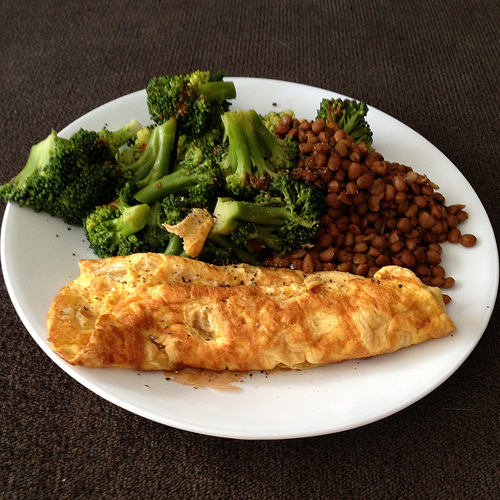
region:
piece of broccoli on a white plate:
[0, 120, 112, 217]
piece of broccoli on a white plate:
[142, 66, 244, 131]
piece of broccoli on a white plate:
[315, 94, 377, 145]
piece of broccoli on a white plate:
[101, 116, 146, 156]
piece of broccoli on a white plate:
[79, 194, 157, 256]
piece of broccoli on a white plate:
[131, 140, 225, 217]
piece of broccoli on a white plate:
[195, 168, 319, 267]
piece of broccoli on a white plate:
[205, 102, 299, 198]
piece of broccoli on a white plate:
[120, 115, 185, 191]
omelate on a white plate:
[45, 244, 458, 384]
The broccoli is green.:
[140, 61, 243, 136]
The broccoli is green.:
[71, 116, 145, 166]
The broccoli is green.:
[3, 124, 78, 213]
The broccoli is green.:
[83, 194, 150, 255]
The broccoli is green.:
[205, 176, 322, 263]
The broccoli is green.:
[121, 132, 221, 207]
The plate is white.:
[1, 67, 498, 442]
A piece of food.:
[353, 237, 370, 257]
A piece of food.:
[372, 237, 392, 249]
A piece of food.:
[384, 227, 416, 252]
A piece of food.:
[390, 217, 411, 235]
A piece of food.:
[397, 204, 424, 222]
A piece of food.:
[378, 185, 395, 203]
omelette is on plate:
[5, 73, 498, 439]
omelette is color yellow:
[50, 253, 459, 366]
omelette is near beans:
[53, 117, 472, 362]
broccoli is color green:
[25, 70, 315, 255]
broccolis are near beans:
[17, 72, 480, 280]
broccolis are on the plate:
[4, 72, 499, 441]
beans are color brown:
[270, 112, 470, 277]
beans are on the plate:
[12, 72, 492, 440]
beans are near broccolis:
[19, 68, 472, 275]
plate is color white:
[5, 77, 495, 442]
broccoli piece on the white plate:
[314, 96, 374, 147]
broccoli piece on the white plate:
[201, 181, 321, 261]